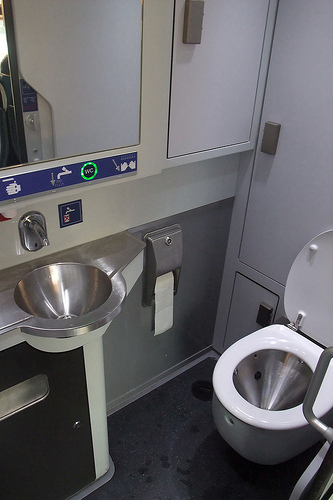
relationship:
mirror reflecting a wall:
[3, 0, 140, 172] [2, 17, 183, 185]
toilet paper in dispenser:
[154, 263, 177, 339] [149, 236, 193, 300]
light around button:
[77, 155, 101, 190] [80, 163, 106, 184]